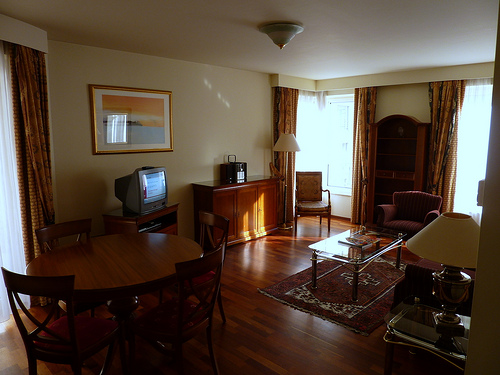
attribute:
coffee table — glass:
[306, 223, 407, 298]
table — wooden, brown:
[26, 239, 211, 299]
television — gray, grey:
[117, 168, 168, 206]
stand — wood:
[108, 208, 175, 234]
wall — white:
[44, 40, 282, 251]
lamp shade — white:
[275, 133, 301, 153]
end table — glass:
[385, 296, 471, 371]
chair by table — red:
[139, 252, 220, 367]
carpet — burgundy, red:
[263, 252, 418, 338]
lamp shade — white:
[406, 212, 480, 268]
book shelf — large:
[367, 114, 425, 227]